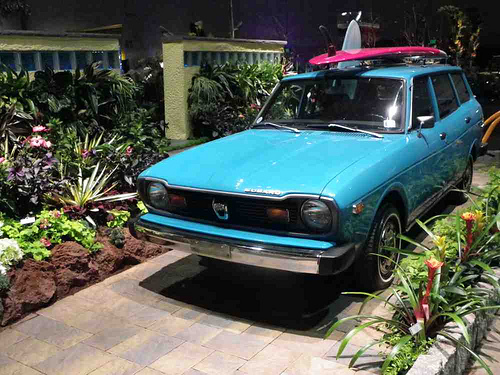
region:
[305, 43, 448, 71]
red surfboard on top of car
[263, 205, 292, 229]
left turn signal on car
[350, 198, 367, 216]
amber side marker on car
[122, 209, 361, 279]
chrome bumper on blue car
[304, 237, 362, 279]
black plastic cap on bumper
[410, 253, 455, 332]
red flowers beside car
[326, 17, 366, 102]
white surfboard leaned against car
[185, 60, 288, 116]
green plants against yellow wall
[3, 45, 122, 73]
row of windows in yellow wall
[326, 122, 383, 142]
chrome wiper on car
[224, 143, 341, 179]
The car is blue.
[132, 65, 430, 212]
The car is a vintage model.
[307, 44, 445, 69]
A surfboard is on the car.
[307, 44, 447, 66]
The surfboard is pink.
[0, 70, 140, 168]
Plants are next to the car.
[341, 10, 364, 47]
A white surfboard is behind the car.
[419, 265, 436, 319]
The plant is red.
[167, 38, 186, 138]
A wall is behind the plants.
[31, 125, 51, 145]
The flowers are pink.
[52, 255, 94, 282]
Rocks are in front of the plants.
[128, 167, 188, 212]
light of a car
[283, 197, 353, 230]
light of a car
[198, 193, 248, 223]
brand of a car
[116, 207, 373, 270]
bumper of a car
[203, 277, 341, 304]
shadow of a car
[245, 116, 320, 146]
wiper of a car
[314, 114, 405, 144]
wiper of a car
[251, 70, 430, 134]
windshield of a car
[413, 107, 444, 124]
mirror of a car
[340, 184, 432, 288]
wheel of a car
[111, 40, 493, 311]
blue paint on the car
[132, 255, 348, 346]
shadow on the ground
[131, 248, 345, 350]
shadow from the car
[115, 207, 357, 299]
silver bumper on the front of the car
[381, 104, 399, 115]
light glare on the windshield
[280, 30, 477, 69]
surfboard on top of the car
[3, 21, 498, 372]
car parked in a driveway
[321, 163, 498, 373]
plants along side the driveway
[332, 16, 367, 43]
top of a white surfboard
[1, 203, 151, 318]
rocks alongside the driveway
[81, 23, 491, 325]
an old model car sitting in a driveway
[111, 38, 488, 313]
a car with a surfboard on its roof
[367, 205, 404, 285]
the front wheel of a car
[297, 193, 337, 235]
the headlight of a car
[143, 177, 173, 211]
the headlight of a car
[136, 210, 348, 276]
the bumper of a car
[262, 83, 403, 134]
the windshield of a car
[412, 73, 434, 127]
the driver's side window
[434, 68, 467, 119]
side windows of a car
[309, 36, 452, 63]
a pink surfboard